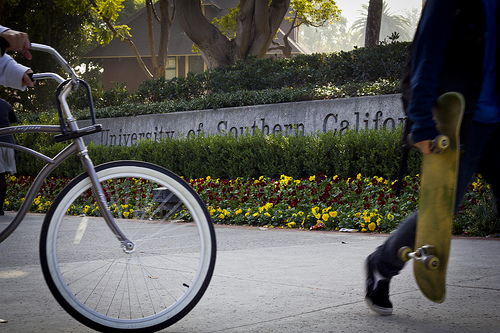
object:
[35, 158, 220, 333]
tire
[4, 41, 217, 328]
bicycle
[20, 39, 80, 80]
handle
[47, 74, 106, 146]
lock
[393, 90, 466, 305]
skateboard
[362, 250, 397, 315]
shoe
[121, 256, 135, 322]
spokes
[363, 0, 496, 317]
person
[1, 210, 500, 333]
sidewalk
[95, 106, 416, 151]
signs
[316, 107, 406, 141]
california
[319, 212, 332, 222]
flowers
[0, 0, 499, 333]
background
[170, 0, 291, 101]
trunk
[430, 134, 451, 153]
wheels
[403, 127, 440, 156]
hands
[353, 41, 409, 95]
bushes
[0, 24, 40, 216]
person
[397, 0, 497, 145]
shirt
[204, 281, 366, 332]
crack